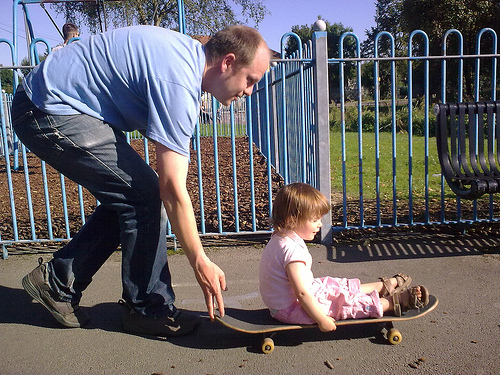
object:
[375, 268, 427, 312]
sandals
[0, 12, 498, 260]
railing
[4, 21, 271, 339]
man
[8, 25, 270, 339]
father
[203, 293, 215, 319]
finger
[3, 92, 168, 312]
jeans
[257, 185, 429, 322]
girl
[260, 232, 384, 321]
pink outfit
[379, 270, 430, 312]
brown sandals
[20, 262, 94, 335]
brown boot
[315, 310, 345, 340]
hand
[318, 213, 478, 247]
shadow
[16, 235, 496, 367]
sidewalk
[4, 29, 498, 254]
fence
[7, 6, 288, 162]
tee shirt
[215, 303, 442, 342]
skateboard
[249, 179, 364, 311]
kid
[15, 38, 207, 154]
shirt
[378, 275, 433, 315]
shoes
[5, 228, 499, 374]
walkway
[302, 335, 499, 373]
wood chips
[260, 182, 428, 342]
child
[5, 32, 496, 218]
fencing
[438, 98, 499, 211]
bench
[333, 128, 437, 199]
area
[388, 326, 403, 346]
wheel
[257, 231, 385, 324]
outfit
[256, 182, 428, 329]
daughter